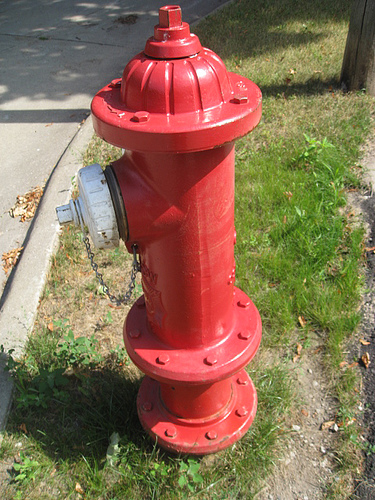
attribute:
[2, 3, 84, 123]
road — tarmacked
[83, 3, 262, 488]
hydrant — red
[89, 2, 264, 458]
fire hydrant — red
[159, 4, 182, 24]
bolt — red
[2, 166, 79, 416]
curb — concrete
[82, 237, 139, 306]
chain — pictured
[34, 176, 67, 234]
leaves — brown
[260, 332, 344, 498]
patch — dirt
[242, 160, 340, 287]
grass — green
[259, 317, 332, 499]
soil — pictured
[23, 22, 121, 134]
road — pictured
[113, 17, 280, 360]
hydrant — red, fire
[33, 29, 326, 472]
hydrant — fire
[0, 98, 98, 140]
shadow — pole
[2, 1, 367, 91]
shadow — tree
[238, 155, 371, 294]
grass — pictured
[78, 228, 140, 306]
chain — metal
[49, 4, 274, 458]
hydrant — fire, red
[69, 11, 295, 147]
cap — white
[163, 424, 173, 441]
bolt — ground